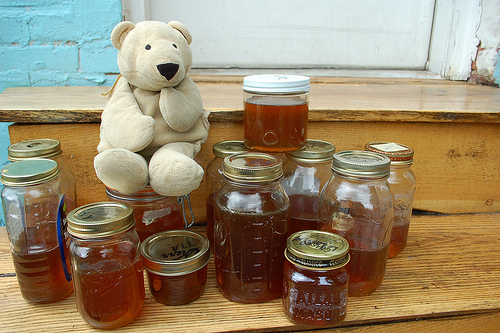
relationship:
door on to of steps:
[195, 7, 438, 69] [354, 80, 496, 136]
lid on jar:
[243, 72, 313, 97] [238, 70, 311, 155]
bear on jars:
[93, 20, 210, 197] [13, 124, 455, 330]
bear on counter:
[93, 20, 210, 197] [1, 209, 499, 327]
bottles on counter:
[1, 69, 422, 331] [1, 209, 499, 327]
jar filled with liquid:
[279, 228, 349, 325] [282, 262, 349, 322]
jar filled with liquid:
[210, 150, 291, 304] [218, 212, 285, 299]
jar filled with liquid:
[66, 200, 143, 330] [76, 250, 141, 324]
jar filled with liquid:
[242, 73, 309, 151] [244, 97, 308, 149]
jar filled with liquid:
[318, 151, 399, 298] [348, 250, 385, 294]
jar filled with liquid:
[364, 140, 416, 259] [391, 225, 407, 252]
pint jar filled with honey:
[285, 231, 352, 326] [283, 255, 352, 326]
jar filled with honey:
[318, 156, 399, 313] [348, 237, 383, 284]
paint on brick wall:
[3, 0, 123, 176] [0, 1, 122, 228]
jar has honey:
[279, 228, 349, 325] [243, 94, 308, 153]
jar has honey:
[210, 150, 290, 302] [243, 94, 308, 153]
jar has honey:
[242, 73, 309, 151] [243, 94, 308, 153]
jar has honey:
[66, 200, 143, 330] [243, 94, 308, 153]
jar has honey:
[138, 229, 211, 305] [243, 94, 308, 153]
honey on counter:
[213, 72, 414, 331] [9, 81, 499, 328]